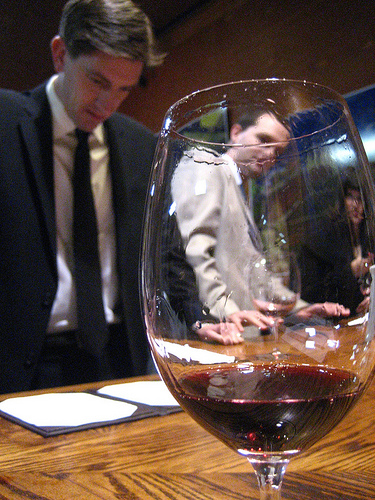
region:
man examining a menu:
[6, 10, 224, 492]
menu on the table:
[13, 373, 203, 459]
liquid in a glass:
[186, 353, 338, 463]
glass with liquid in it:
[131, 79, 373, 494]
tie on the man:
[64, 126, 112, 364]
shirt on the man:
[44, 84, 125, 335]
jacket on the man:
[1, 87, 179, 360]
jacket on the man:
[178, 140, 286, 316]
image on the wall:
[145, 95, 234, 202]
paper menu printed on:
[6, 398, 113, 418]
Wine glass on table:
[141, 75, 372, 488]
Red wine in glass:
[171, 365, 356, 448]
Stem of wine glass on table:
[240, 457, 291, 498]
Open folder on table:
[5, 378, 176, 435]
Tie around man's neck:
[70, 129, 110, 355]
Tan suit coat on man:
[168, 148, 301, 320]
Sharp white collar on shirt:
[49, 80, 106, 147]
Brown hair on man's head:
[57, 1, 160, 63]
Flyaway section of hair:
[152, 50, 167, 66]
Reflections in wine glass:
[241, 419, 303, 458]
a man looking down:
[44, 1, 171, 154]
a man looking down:
[203, 88, 298, 221]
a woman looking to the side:
[326, 162, 372, 230]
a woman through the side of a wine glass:
[336, 158, 374, 231]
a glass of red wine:
[141, 78, 371, 490]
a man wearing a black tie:
[43, 1, 152, 359]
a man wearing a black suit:
[0, 0, 188, 385]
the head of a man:
[225, 92, 293, 179]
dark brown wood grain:
[105, 473, 134, 498]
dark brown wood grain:
[133, 470, 173, 499]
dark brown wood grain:
[143, 471, 194, 497]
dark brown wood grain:
[173, 472, 238, 497]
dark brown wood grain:
[188, 471, 253, 496]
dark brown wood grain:
[39, 470, 67, 481]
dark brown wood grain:
[351, 439, 373, 454]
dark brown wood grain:
[304, 430, 359, 459]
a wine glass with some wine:
[141, 93, 363, 476]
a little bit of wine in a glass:
[186, 358, 321, 466]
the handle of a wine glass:
[249, 446, 291, 498]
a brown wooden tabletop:
[146, 445, 197, 486]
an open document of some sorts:
[0, 384, 166, 442]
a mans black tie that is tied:
[65, 143, 115, 379]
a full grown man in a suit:
[182, 102, 333, 320]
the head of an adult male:
[27, 17, 167, 129]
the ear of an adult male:
[40, 33, 73, 71]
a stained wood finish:
[1, 447, 42, 498]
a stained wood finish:
[43, 449, 82, 498]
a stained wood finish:
[84, 448, 125, 497]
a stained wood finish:
[124, 444, 169, 497]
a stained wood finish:
[169, 441, 203, 497]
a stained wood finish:
[201, 443, 243, 497]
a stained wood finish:
[280, 449, 314, 498]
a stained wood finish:
[321, 436, 359, 496]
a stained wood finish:
[327, 442, 373, 487]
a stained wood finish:
[132, 398, 189, 443]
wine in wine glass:
[163, 355, 367, 454]